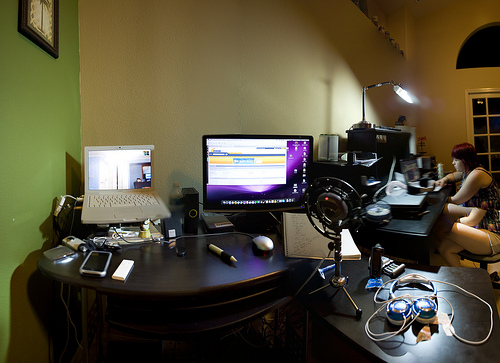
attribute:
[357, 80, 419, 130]
lamp — turned on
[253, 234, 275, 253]
computer mouse — white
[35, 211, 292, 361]
table — large , round 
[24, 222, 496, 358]
desk — dark, wood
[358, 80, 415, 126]
light — overhead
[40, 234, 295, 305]
table — round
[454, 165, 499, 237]
strap top — spaghetti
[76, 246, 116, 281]
smartphone — gray,  black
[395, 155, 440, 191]
loptop — black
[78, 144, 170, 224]
laptop — white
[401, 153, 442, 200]
laptop — black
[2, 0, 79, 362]
wall — lime, green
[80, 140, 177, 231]
laptop — gray